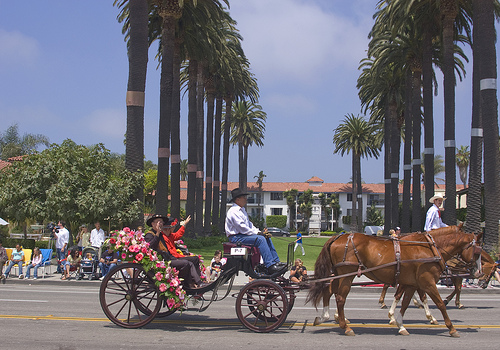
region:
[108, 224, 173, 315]
pink roses on a carriage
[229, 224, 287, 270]
blue pants on a man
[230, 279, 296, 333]
wheels on the front of a carriage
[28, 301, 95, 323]
ellow lines on the asphalt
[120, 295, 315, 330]
shadow from a carraige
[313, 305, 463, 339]
shadow from horses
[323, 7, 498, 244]
row of very tall palm trees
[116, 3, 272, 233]
row of very tall palm trees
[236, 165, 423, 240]
house in the distance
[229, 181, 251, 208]
black hat on a man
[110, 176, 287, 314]
people riding on a carriage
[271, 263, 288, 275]
black shoes on feet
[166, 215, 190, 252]
red jacket on woman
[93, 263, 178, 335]
large brown wheel of carriage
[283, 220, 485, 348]
two horses pulling carraige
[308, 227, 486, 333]
two brown horses pulling carriage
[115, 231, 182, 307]
flowers decorating a carriage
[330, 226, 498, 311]
horses pulling a carriage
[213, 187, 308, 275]
a guy driving a carriage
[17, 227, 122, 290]
people standing on the sidewalk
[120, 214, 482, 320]
a carriage of people passing an audieance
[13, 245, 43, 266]
kids sitting in a chair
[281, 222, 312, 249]
a person walking on a field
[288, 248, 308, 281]
a person sitting on the sidewalk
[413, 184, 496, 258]
a guy riding a horse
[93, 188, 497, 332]
Two Horses and a buggy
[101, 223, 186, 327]
Pink and red flowers on buggy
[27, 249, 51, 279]
Girl sitting in blue chair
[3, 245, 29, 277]
Person sitting in yellow chair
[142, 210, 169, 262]
Man wearing hat waving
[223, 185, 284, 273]
Man wearing black hat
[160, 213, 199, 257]
Person wearing red waving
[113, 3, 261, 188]
Row of tall palm trees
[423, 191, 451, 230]
Man with white shirt and white hat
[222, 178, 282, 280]
man sitting on front of carriage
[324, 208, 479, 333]
two horses pulling a carriage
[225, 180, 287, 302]
man wearing black cowboy hat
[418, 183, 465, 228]
man riding on a horse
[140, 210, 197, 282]
man waving his hand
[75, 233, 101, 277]
baby sitting in stroller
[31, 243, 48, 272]
girl sitting in a chair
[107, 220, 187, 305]
flowers on side of carriage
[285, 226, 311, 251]
man walking across the grass